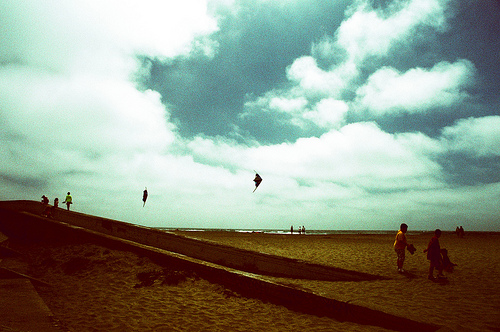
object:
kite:
[251, 168, 264, 194]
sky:
[1, 0, 500, 188]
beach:
[60, 283, 498, 331]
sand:
[0, 233, 497, 332]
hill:
[1, 199, 390, 332]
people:
[39, 190, 74, 211]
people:
[387, 222, 463, 282]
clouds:
[0, 0, 499, 169]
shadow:
[399, 270, 452, 286]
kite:
[140, 186, 150, 208]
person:
[390, 222, 418, 277]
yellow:
[390, 230, 412, 251]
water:
[152, 227, 327, 235]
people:
[287, 223, 310, 236]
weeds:
[135, 262, 193, 288]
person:
[60, 190, 77, 212]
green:
[66, 195, 73, 203]